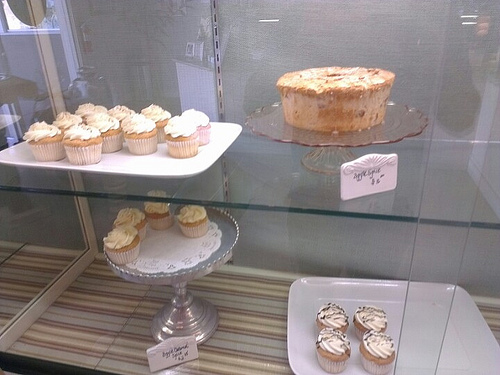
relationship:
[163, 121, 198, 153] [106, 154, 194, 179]
cupcake on plate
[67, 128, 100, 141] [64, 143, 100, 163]
frosting on cupcake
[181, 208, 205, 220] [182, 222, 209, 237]
frosting on cupcake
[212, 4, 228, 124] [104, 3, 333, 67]
beam on wall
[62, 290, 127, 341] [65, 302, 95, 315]
wall paper has stripe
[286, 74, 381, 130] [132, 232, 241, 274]
cake on platter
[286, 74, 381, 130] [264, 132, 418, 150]
cake on platter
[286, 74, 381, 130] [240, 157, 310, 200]
cake on shelf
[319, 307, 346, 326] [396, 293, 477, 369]
cupcake on tray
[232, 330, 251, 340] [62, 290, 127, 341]
stripe on wall paper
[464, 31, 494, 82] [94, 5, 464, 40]
reflection on glass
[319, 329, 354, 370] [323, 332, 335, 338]
cupcake has frosting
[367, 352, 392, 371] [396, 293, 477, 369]
cupcake on tray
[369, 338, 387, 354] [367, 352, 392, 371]
frosting on cupcake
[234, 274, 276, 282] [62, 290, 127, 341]
stripe on wall paper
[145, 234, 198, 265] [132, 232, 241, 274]
doliy on platter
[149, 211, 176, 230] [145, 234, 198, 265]
cupcake on doliy